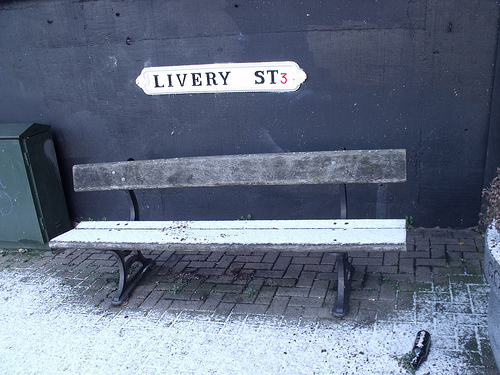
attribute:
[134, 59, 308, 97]
sign — white, rectangular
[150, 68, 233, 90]
lettering — black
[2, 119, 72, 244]
trashcan — green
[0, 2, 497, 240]
wall — gray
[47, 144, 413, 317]
bench — lopsided, old, wooden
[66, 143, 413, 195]
backrest — plank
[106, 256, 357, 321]
feet — metal, black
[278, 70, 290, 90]
number — red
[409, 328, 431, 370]
bottle — glass, abandoned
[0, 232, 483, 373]
ground — brick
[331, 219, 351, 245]
screws — metal